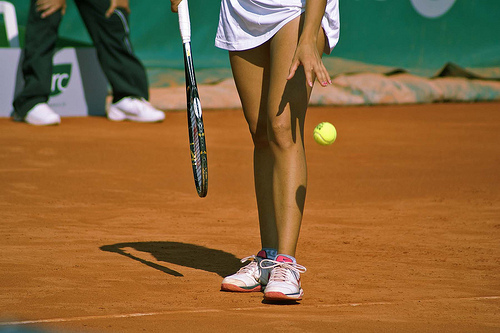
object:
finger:
[169, 0, 182, 14]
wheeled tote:
[0, 43, 111, 119]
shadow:
[98, 240, 249, 278]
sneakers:
[26, 100, 64, 126]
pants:
[12, 0, 149, 112]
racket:
[175, 0, 209, 199]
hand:
[168, 0, 182, 12]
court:
[0, 92, 500, 333]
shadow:
[275, 66, 311, 145]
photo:
[0, 0, 500, 333]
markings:
[0, 292, 500, 328]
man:
[11, 0, 166, 127]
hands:
[283, 46, 337, 88]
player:
[171, 0, 342, 303]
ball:
[312, 121, 337, 145]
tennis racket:
[176, 0, 209, 199]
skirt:
[212, 0, 340, 54]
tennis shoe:
[264, 253, 303, 304]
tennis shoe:
[221, 251, 268, 292]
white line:
[0, 295, 499, 328]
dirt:
[0, 99, 499, 333]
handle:
[177, 0, 192, 43]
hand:
[104, 0, 132, 17]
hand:
[33, 0, 67, 18]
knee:
[96, 12, 131, 37]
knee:
[32, 11, 64, 30]